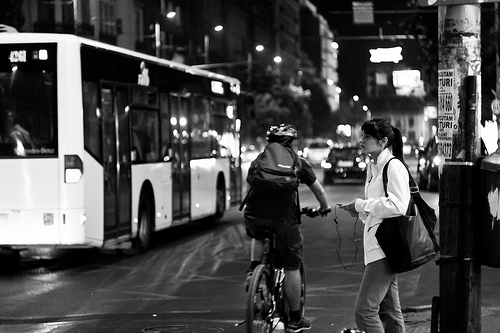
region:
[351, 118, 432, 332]
Girl standing near street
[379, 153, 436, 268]
Bag over girl's shoulder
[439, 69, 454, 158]
White poster on metal pole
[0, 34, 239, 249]
Large white bus on street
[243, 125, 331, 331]
Bicyclist waiting on street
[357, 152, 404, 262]
White shirt on girl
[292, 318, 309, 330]
Black shoe on bicyclist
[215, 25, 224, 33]
Glowing street light over street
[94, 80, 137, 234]
Back door on bus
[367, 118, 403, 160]
Dark hair in ponytail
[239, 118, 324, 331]
Man riding bike down road.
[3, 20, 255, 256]
Large bus driving down the road.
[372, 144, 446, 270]
Purse on woman's shoulder.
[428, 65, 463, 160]
Sign on the a pole.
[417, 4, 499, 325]
Large metal pole on sidewalk.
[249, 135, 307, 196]
Backpack on a man's back.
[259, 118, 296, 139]
Helmet on a man's had.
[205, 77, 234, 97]
Sign on the side of a bus.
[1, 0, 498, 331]
A scene is in black and white.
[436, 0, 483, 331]
A pole has posters on it.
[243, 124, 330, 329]
A man is riding a bicycle.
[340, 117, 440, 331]
A woman is carrying a bag on her shoulder.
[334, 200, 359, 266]
A hand has dangling wires.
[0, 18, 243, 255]
A black and white bus is on the street.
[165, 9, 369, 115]
Lights in a row are on.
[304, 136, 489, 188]
Three cars are behind a woman.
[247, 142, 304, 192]
A backpack is on a back.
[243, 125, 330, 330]
A bike rider is wearing a helmet.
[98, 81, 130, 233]
door on the bus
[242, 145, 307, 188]
backpack on the biker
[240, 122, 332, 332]
biker riding bike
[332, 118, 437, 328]
woman holding electronic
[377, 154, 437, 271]
purse on woman's shoulder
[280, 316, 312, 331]
shoe on the biker's foot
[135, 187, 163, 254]
tire on the bus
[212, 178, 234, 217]
wheel on the bus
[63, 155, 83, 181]
light on the bus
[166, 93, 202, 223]
door on the bus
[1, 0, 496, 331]
A black and white photo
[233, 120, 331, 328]
A person riding a bike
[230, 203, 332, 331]
A bicycle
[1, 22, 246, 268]
A city bus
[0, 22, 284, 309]
A bus driving on the road.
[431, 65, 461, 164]
Advertisements on a pole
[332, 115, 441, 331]
A woman walking with a black bag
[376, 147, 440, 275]
A large dark colored shoulder bag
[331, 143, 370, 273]
Earbud cords.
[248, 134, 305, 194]
A backpack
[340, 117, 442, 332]
woman with bag walking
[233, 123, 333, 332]
man riding on bike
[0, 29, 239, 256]
large white metal bus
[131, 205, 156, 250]
small round black tire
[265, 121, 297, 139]
small round bike helmet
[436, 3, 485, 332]
large tall metal pole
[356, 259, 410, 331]
long cloth grey pants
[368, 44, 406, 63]
large wide white lights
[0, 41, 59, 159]
large square glass window